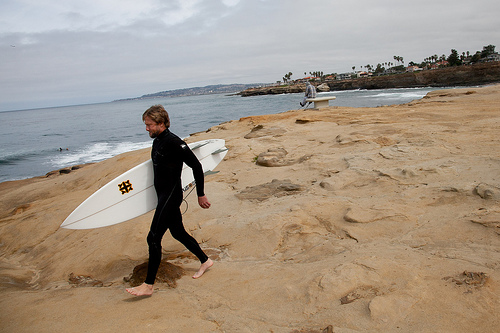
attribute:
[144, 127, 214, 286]
swimsuit — black, uniform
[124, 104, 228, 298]
man — barefoot, surfer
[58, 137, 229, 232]
surfboard — white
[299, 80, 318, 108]
man — seated, sitting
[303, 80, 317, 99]
jumper — grey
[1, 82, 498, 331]
ground — unleveled, lumpy, sandy, brown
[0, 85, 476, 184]
water — colorless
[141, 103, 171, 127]
hair — blonde